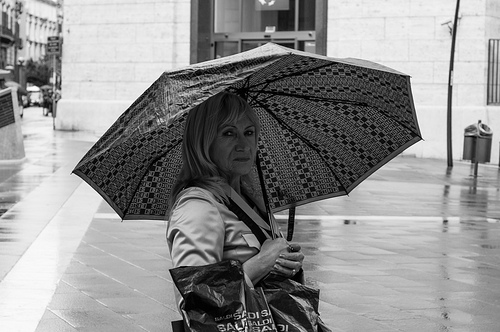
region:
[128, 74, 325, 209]
The woman is under the umbrella.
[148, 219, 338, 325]
The lady has shopping bags in ther hand.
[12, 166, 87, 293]
The ground is wet.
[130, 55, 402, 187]
The umbrella is open.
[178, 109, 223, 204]
The lady has long blonde hair.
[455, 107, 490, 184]
Garbage bins are near the building.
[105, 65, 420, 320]
A lady standing in front of the store.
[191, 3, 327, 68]
The doors of the building.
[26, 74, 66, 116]
People standing on the sidewalk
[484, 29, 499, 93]
An iron railing by the building.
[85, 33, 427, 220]
a black and white umbrella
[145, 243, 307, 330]
a black shopping bag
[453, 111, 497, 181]
two garbage cans on a pole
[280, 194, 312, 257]
a black strap hanging from umbrella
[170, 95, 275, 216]
woman has shoulder length blond hair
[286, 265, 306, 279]
Woman wearing a wedding band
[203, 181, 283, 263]
A black strap coming over the shoulder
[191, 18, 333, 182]
a door to a building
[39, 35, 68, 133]
a sign on a pole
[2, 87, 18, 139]
a black sign on cement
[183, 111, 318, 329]
woman holding shopping bag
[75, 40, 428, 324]
woman holding umbrella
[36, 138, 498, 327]
streets are wet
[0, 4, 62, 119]
building in far distance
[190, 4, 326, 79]
doorway on building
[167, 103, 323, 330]
woman in front of building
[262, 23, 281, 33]
sign on front of building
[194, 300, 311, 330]
words on shopping bag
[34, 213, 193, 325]
pattern on walk way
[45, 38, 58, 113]
sign on post next to building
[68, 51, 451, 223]
umbrella the woman is holding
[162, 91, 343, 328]
woman standing in the rain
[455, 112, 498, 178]
trash can in the background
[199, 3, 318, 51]
door of building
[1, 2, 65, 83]
buildings across the street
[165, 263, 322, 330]
the woman's shopping bags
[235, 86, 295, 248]
handle of the umbrella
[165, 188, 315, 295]
long sleeve shirt the woman is wearing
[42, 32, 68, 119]
street signs in the distance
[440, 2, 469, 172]
pole in the background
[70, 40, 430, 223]
a large colorful umbrella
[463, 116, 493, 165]
a public trashcan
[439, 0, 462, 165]
a large black pole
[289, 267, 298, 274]
a woman's ring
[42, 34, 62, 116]
a tall sign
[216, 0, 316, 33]
a window of a building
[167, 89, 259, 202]
a woman's blonde hair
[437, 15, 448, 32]
a white security camera hanging on a building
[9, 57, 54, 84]
part of a green tree